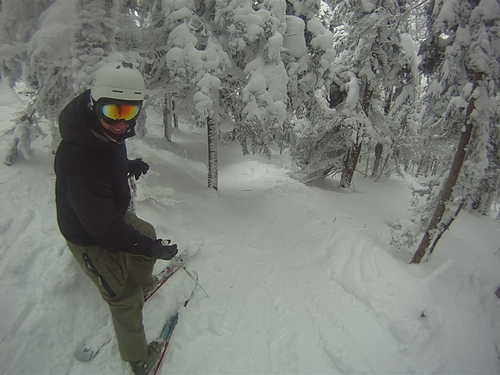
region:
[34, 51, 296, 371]
a man on skies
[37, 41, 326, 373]
a man on the snow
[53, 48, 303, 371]
a man on the white snow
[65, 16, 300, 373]
a man skiing on the snow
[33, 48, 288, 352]
a man skiing on the white snow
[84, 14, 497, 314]
an area of snow and trees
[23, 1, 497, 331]
an area of trees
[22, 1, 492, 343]
trees covered in snow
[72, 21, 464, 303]
trees covered in white snow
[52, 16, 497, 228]
white snow covering trees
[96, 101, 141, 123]
iridescent goggles over a man's eyes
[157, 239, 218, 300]
white ski pole in a man's hand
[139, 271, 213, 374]
ski covered in snow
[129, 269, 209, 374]
ski attached to a man's foot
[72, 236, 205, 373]
skis attached to a man's feet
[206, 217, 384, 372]
lots of tracks in snow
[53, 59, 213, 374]
person on skis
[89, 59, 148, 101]
white helmet on a skier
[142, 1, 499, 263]
lots of trees heavily covered in snow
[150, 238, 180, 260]
black gloves on a skiers hand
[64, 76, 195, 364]
A man snow sketing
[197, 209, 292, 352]
A heap of white snow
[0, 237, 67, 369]
A heap of white snow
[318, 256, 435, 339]
A heap of white snow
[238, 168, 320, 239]
A heap of white snow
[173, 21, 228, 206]
A tree covered with snow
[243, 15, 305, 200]
A tree covered with snow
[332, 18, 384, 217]
A tree covered with snow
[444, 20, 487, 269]
A tree covered with snow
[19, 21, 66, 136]
A tree covered with snow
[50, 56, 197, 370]
a person skiing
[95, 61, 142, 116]
a white hard hat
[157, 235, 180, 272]
a gloved right hand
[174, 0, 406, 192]
snow covered trees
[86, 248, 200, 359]
a skis on feet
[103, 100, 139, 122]
goggles on a head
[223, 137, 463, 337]
a trail of snow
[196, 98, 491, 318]
a trail between trees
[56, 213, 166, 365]
tan pants on a person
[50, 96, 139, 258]
a black hood on a person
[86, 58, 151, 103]
Man wearing white helmet.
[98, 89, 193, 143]
Man wearing goggles on face.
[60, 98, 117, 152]
Coat has black hood.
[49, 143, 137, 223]
Person wearing black coat.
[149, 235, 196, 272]
Person wearing black gloves.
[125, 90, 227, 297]
Person holding ski poles.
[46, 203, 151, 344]
Person wearing gray pants.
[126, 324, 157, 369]
Person wearing gray boots.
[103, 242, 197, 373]
Person wearing skis on feet.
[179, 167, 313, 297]
Ground is covered in snow.